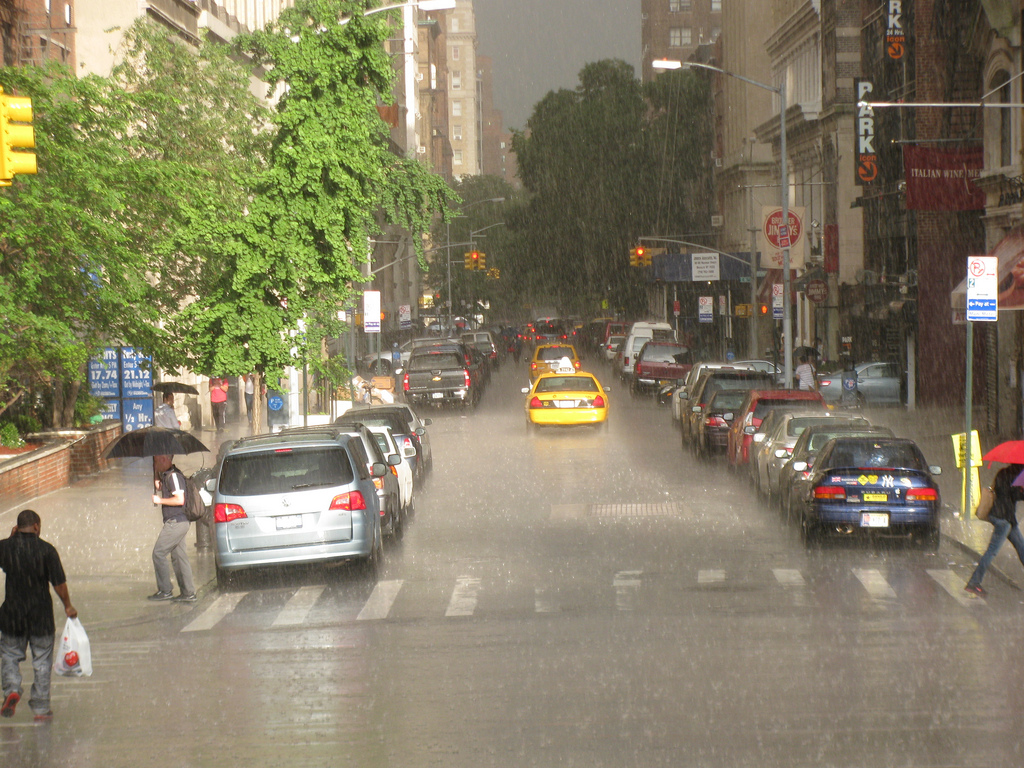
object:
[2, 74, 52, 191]
light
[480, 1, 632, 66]
sky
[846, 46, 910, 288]
sign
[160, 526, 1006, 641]
stripes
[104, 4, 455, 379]
leaves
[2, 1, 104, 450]
tree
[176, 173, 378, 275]
leaves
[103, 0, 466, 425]
tree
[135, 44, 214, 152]
leaves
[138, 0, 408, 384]
tree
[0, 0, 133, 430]
tree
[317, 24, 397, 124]
leaves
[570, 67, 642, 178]
leaves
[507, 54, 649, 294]
tree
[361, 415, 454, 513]
car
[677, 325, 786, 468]
car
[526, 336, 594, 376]
car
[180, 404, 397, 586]
car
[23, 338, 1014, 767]
street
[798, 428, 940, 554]
car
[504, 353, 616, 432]
car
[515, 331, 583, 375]
car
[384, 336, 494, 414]
car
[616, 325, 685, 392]
car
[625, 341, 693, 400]
car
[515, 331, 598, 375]
taxi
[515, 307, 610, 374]
taxi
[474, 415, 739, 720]
road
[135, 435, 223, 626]
person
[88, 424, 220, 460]
umbrella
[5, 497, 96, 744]
person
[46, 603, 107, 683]
bag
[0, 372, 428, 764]
sidewalk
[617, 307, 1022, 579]
sidewalk